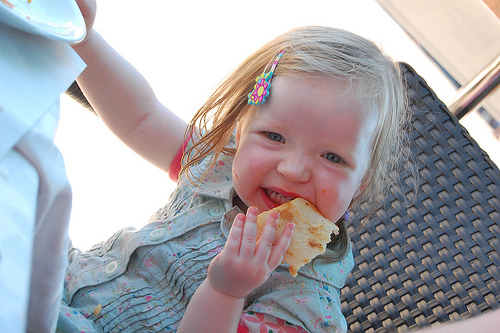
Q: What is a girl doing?
A: Eating.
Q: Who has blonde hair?
A: The girl.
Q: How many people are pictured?
A: One.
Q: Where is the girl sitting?
A: On a chair.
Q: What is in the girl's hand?
A: Food.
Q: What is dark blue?
A: Chair.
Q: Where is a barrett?
A: In girl's hair.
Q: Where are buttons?
A: On girl's shirt.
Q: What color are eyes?
A: Blue.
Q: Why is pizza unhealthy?
A: It is greasy.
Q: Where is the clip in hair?
A: On the side.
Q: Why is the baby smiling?
A: The baby is happy.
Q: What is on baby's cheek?
A: Pizza sauce.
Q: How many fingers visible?
A: 4.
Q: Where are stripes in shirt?
A: On sides.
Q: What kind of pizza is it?
A: Cheese.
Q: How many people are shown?
A: One.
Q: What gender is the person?
A: Female.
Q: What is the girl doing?
A: Eating.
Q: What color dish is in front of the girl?
A: White.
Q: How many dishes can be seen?
A: One.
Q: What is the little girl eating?
A: Pizza.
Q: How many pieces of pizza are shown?
A: One.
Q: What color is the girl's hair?
A: Blonde.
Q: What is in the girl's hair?
A: Hair clip.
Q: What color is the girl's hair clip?
A: Blue, pink, and yellow.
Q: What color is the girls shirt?
A: Blue and floral.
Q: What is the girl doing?
A: Eating.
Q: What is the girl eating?
A: Bread.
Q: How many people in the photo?
A: One.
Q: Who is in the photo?
A: A girl.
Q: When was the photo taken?
A: During the day.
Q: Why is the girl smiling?
A: She's happy.